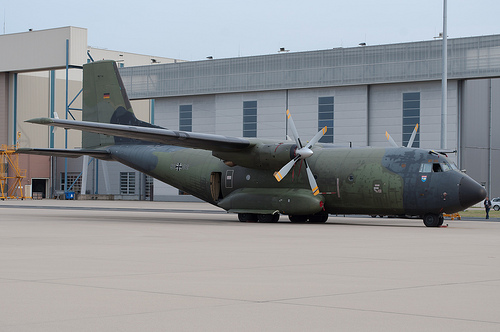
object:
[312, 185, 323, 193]
stripes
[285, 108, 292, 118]
stripes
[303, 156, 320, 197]
blade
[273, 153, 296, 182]
blade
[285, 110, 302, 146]
blade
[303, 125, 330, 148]
blade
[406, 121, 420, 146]
blade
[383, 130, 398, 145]
propeller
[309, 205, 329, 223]
tires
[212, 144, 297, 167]
plane engine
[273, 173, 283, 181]
stripes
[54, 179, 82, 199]
corvette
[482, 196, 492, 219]
person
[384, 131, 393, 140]
stripes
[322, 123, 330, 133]
stripes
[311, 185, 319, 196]
stripes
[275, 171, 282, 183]
stripes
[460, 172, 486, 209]
nose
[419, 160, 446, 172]
cockpit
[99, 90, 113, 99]
flag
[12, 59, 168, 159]
tail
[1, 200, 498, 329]
tarmac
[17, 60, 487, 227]
airplane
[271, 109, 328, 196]
propeller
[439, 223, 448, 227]
wheel stopper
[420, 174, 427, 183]
flag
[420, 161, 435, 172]
window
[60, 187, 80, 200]
fence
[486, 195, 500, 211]
car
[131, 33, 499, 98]
fence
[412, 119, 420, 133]
stripes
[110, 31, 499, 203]
building